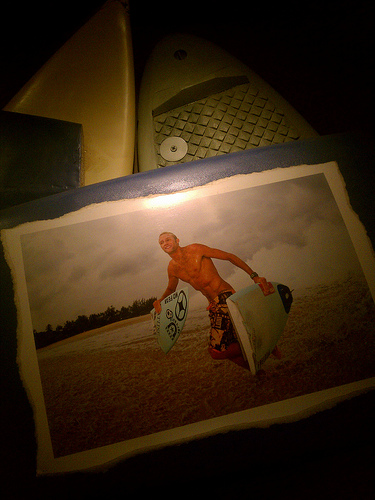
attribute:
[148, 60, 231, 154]
board — small, green, diamond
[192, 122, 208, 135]
diamond — green, Small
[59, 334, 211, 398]
beach — tan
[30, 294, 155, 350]
tree grove — green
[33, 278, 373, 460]
sand — brown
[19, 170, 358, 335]
sky — gray, cloudy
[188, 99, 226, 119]
diamond — green, Small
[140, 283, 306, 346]
surfboard — white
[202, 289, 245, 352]
trunks — patterned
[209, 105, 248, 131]
diamond — Small, green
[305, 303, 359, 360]
sand — brown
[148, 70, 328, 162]
board — small, green, diamond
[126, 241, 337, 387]
surf board — half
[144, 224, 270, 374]
man — shirtless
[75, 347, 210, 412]
sand — brown